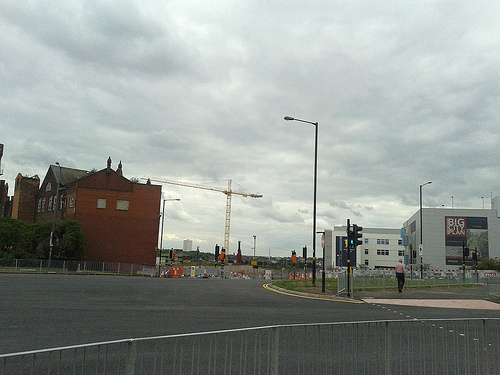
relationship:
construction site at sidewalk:
[157, 248, 323, 268] [6, 271, 498, 369]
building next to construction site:
[0, 156, 163, 274] [167, 244, 310, 281]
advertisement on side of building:
[443, 215, 490, 266] [324, 187, 498, 279]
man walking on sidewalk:
[389, 261, 409, 288] [6, 271, 498, 369]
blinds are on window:
[93, 195, 114, 213] [111, 194, 133, 210]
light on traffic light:
[345, 236, 360, 247] [346, 218, 364, 301]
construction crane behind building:
[148, 173, 268, 258] [0, 156, 163, 274]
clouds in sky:
[388, 3, 498, 75] [2, 1, 499, 258]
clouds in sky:
[389, 102, 489, 189] [2, 1, 499, 258]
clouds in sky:
[60, 7, 175, 67] [2, 1, 499, 258]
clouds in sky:
[131, 107, 269, 189] [2, 1, 499, 258]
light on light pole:
[281, 114, 295, 124] [311, 121, 318, 286]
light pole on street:
[311, 121, 318, 286] [4, 257, 498, 374]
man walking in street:
[393, 258, 408, 293] [4, 257, 498, 374]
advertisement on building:
[443, 215, 490, 266] [404, 204, 499, 270]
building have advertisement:
[324, 187, 498, 279] [443, 215, 490, 266]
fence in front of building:
[0, 259, 164, 277] [36, 172, 186, 274]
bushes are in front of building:
[0, 218, 86, 271] [63, 155, 162, 272]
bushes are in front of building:
[0, 218, 86, 271] [33, 164, 89, 220]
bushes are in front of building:
[0, 218, 86, 271] [0, 172, 39, 221]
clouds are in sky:
[197, 36, 407, 96] [128, 73, 295, 161]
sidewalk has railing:
[6, 271, 498, 369] [0, 318, 499, 373]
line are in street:
[370, 300, 493, 349] [76, 272, 259, 364]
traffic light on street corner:
[346, 218, 364, 301] [264, 270, 444, 312]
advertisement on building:
[443, 215, 490, 266] [385, 210, 498, 280]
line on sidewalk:
[260, 281, 365, 305] [6, 271, 498, 369]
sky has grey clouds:
[72, 26, 454, 120] [34, 13, 498, 135]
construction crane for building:
[139, 175, 263, 263] [10, 164, 162, 274]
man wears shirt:
[393, 258, 408, 293] [393, 261, 405, 273]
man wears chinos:
[393, 258, 408, 293] [387, 270, 417, 297]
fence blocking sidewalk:
[0, 316, 499, 374] [6, 271, 498, 369]